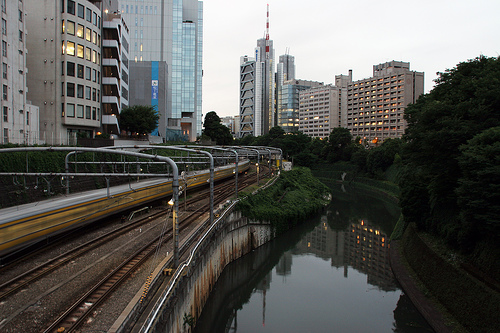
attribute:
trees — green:
[111, 51, 497, 287]